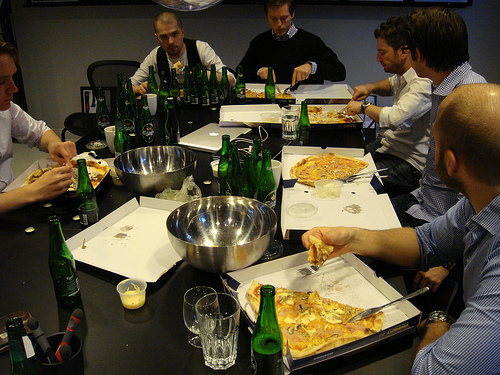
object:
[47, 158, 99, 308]
glass bottles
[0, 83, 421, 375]
table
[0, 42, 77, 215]
guy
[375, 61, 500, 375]
shirts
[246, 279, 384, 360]
pizza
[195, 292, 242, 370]
glass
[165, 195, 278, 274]
bowl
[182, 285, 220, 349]
glass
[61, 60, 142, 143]
chair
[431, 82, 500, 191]
head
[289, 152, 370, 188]
pizza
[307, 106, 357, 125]
pizza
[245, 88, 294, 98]
pizza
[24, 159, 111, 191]
pizza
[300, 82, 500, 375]
man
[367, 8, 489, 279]
man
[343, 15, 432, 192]
man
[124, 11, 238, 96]
man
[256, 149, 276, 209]
bottle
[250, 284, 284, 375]
bottle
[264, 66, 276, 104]
bottle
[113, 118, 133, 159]
bottle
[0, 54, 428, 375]
pizza dinner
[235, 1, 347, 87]
man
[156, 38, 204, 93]
vest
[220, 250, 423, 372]
box